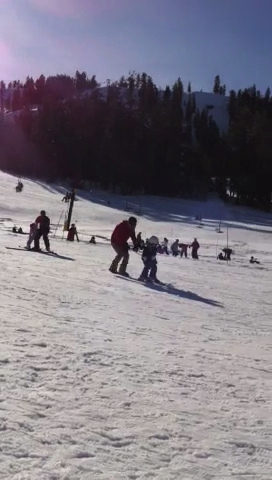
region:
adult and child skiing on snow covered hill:
[101, 206, 177, 298]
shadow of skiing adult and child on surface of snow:
[110, 258, 226, 321]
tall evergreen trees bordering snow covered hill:
[1, 60, 271, 207]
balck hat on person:
[126, 213, 138, 226]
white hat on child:
[144, 233, 161, 246]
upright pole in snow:
[60, 166, 82, 234]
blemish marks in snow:
[24, 339, 144, 398]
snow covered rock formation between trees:
[8, 84, 255, 172]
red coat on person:
[104, 217, 137, 250]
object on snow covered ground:
[84, 232, 100, 247]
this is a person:
[22, 204, 65, 251]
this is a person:
[18, 215, 45, 252]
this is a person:
[102, 204, 139, 282]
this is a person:
[139, 232, 170, 291]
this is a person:
[189, 229, 206, 260]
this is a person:
[170, 235, 191, 262]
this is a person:
[245, 250, 264, 273]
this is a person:
[213, 237, 240, 270]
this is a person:
[62, 220, 79, 244]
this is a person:
[126, 225, 145, 257]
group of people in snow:
[14, 165, 240, 309]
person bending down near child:
[100, 216, 170, 282]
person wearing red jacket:
[100, 216, 146, 250]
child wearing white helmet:
[143, 231, 160, 248]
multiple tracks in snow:
[42, 275, 218, 460]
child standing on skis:
[12, 215, 46, 270]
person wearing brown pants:
[107, 239, 134, 279]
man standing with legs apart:
[29, 225, 54, 254]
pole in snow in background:
[52, 177, 87, 245]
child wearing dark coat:
[137, 243, 163, 270]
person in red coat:
[104, 213, 140, 279]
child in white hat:
[136, 233, 165, 284]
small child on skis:
[137, 234, 175, 290]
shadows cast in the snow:
[111, 267, 225, 313]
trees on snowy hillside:
[0, 70, 270, 214]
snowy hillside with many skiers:
[0, 165, 270, 475]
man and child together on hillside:
[22, 209, 56, 255]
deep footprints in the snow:
[71, 434, 131, 460]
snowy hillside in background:
[1, 64, 270, 197]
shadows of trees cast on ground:
[33, 174, 271, 232]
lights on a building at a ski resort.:
[158, 80, 268, 205]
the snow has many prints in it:
[0, 244, 270, 479]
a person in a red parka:
[112, 213, 132, 244]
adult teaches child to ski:
[110, 215, 172, 285]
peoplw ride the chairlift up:
[0, 161, 30, 213]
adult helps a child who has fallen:
[215, 243, 234, 262]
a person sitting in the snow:
[248, 252, 262, 267]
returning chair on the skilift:
[215, 215, 229, 239]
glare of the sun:
[3, 79, 140, 124]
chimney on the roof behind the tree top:
[110, 79, 133, 91]